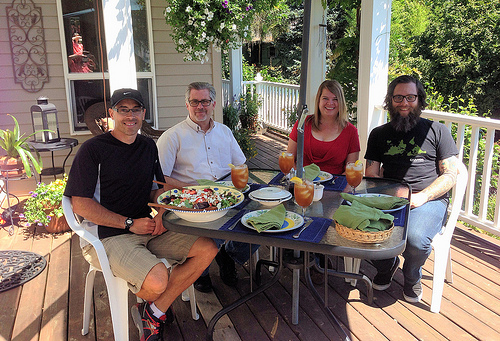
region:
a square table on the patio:
[161, 165, 412, 340]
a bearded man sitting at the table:
[365, 74, 459, 300]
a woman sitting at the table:
[286, 77, 360, 174]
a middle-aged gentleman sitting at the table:
[155, 80, 247, 190]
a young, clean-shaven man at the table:
[64, 86, 218, 339]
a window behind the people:
[56, 0, 159, 135]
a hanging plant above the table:
[161, 0, 268, 64]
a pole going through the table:
[291, 1, 315, 324]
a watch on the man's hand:
[123, 216, 133, 228]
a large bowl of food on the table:
[146, 177, 243, 222]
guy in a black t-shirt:
[55, 79, 222, 334]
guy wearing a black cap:
[64, 85, 223, 339]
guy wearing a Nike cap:
[64, 89, 214, 337]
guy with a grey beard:
[147, 80, 249, 202]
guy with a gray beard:
[157, 77, 248, 221]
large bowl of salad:
[139, 172, 253, 229]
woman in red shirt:
[268, 73, 361, 182]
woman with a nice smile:
[275, 81, 362, 189]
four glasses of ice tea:
[227, 142, 369, 213]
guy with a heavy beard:
[362, 76, 465, 312]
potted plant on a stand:
[0, 112, 52, 219]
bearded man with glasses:
[379, 75, 433, 150]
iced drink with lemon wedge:
[284, 173, 321, 220]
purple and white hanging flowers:
[162, 1, 264, 66]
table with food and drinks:
[160, 158, 410, 251]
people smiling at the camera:
[72, 75, 440, 142]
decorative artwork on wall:
[2, 0, 59, 94]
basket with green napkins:
[327, 200, 399, 253]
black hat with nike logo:
[89, 75, 150, 116]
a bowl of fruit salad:
[166, 175, 235, 230]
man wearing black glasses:
[364, 75, 430, 132]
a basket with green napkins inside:
[321, 207, 396, 252]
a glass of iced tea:
[279, 170, 316, 215]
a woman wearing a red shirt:
[275, 78, 365, 177]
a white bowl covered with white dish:
[255, 179, 290, 209]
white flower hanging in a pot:
[137, 0, 256, 82]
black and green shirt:
[369, 118, 467, 221]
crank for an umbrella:
[272, 100, 320, 187]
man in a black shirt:
[64, 73, 174, 255]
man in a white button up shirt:
[156, 59, 254, 210]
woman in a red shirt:
[289, 70, 361, 179]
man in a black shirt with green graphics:
[363, 65, 469, 203]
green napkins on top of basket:
[321, 202, 402, 247]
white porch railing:
[465, 107, 497, 246]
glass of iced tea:
[339, 157, 374, 200]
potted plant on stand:
[2, 106, 45, 191]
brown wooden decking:
[345, 305, 475, 339]